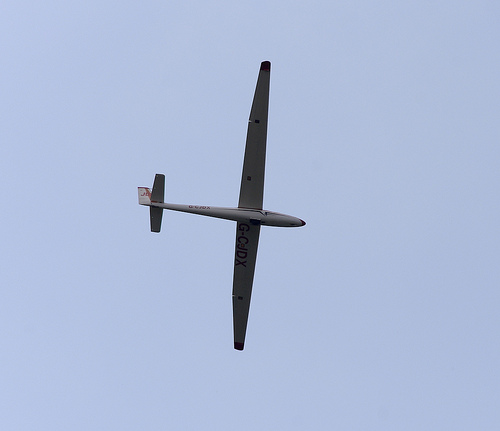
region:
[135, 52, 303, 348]
A plane in the sky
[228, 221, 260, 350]
The wing of a plane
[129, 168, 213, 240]
The back end of a plane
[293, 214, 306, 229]
The nose of a plane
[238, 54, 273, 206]
The wing of a plane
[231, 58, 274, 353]
The wings on a plane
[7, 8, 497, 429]
A clear, blue sky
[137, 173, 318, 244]
The underside of a plane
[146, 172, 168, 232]
The back wings of a plane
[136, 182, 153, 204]
Vertical stabilizer on a plane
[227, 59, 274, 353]
The plane has very long wings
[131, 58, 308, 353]
The plane has no engines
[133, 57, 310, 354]
Glider plane in flight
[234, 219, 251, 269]
Identification on the wing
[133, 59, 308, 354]
Gray plane with some red details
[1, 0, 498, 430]
No clouds in the sky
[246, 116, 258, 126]
Part in the wing with steering mechanism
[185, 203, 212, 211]
Writing on the side of the plane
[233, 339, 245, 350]
Color on the tip of the wing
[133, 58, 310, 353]
Plane is much wider than it is long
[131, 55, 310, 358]
glider in the sky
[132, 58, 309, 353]
underside of a glider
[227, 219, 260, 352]
left wing of the glider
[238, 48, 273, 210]
right wing of the glider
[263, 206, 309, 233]
nose of the glider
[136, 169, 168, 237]
tail of the glider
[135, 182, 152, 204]
red markings on the tail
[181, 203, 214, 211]
writing on the side of the glider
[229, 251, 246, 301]
flap on the glider wing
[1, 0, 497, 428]
there are no clouds in the sky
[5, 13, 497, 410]
a scene outside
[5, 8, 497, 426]
a blue sky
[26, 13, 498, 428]
a gray plane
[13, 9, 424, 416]
a plane flying in the air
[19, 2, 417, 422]
a plane that is pointing right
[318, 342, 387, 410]
A foggy sky in the background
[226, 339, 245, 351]
A black tip of the wing of an airplane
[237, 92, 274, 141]
A long wing of an airplane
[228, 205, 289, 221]
A black line design at the side of the plane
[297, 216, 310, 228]
A red covered tip of an airplane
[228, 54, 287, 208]
A slender wing of an airplane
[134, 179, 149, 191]
Tip of the tail of an airplane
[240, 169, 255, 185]
A black square at the wing of the plane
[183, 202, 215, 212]
A red markings on the side of a plane